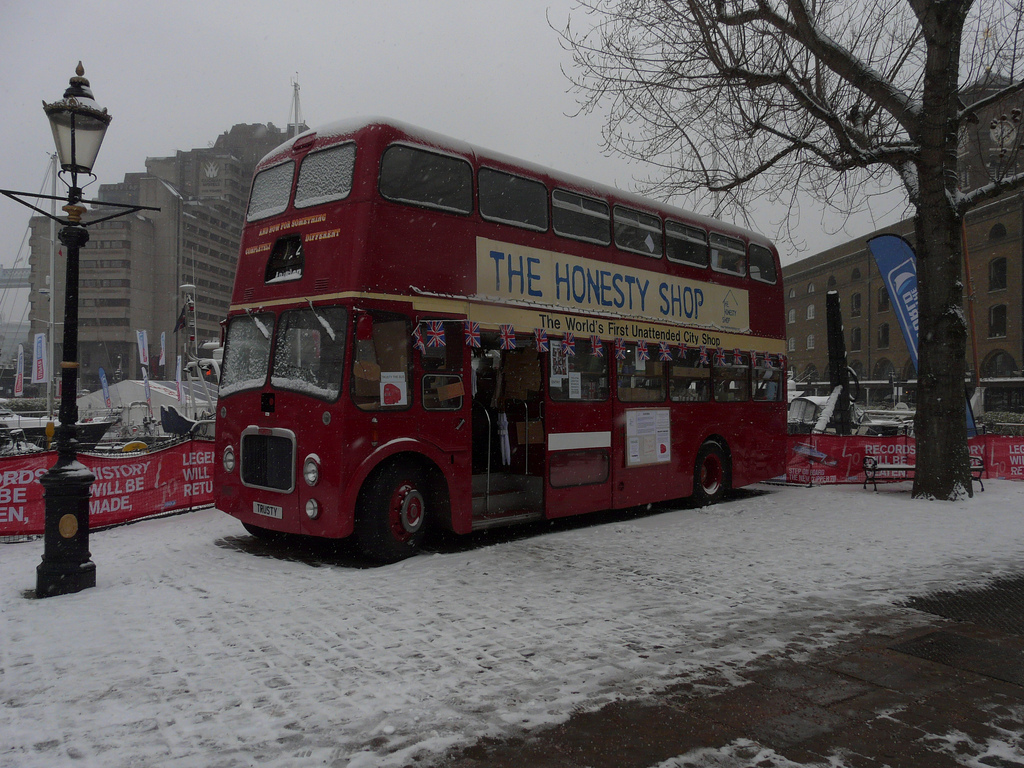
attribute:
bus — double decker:
[200, 47, 859, 655]